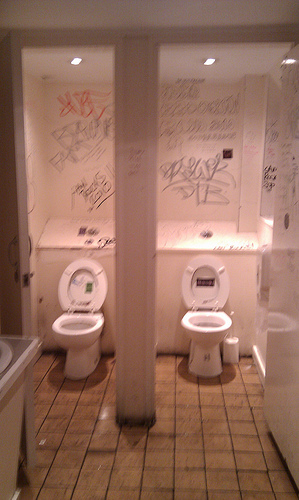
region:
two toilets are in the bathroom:
[36, 249, 254, 380]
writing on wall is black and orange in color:
[14, 92, 295, 250]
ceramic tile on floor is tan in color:
[37, 414, 286, 491]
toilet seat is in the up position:
[50, 257, 117, 362]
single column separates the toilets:
[112, 43, 160, 424]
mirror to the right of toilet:
[267, 68, 293, 323]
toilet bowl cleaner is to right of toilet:
[222, 312, 245, 363]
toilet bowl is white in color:
[49, 311, 107, 368]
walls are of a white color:
[17, 154, 263, 247]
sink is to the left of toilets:
[0, 332, 42, 387]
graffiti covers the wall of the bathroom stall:
[48, 87, 114, 246]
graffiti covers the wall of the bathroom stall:
[158, 80, 240, 212]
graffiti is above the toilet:
[159, 74, 240, 208]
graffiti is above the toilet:
[41, 83, 115, 213]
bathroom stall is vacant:
[17, 43, 122, 415]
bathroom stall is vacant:
[158, 47, 263, 416]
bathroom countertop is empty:
[0, 332, 44, 497]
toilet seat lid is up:
[54, 255, 106, 313]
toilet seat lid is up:
[181, 253, 230, 312]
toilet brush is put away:
[221, 309, 239, 363]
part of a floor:
[249, 486, 254, 490]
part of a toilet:
[201, 361, 203, 366]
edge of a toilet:
[203, 338, 209, 348]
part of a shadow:
[96, 396, 109, 407]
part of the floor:
[175, 478, 185, 494]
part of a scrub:
[233, 345, 236, 352]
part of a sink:
[17, 394, 43, 414]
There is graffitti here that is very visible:
[183, 75, 201, 145]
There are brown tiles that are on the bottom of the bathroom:
[183, 411, 201, 448]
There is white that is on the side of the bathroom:
[278, 346, 287, 389]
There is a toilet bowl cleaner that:
[223, 311, 240, 365]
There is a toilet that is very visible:
[186, 250, 237, 370]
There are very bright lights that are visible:
[202, 47, 225, 84]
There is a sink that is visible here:
[7, 336, 18, 392]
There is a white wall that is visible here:
[11, 191, 50, 234]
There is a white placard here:
[109, 326, 178, 421]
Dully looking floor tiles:
[172, 384, 251, 479]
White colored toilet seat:
[179, 309, 237, 383]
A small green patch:
[84, 279, 94, 293]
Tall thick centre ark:
[109, 222, 158, 427]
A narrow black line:
[173, 394, 175, 497]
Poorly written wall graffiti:
[161, 89, 240, 148]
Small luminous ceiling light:
[67, 53, 89, 70]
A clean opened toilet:
[179, 251, 233, 380]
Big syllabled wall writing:
[156, 147, 239, 207]